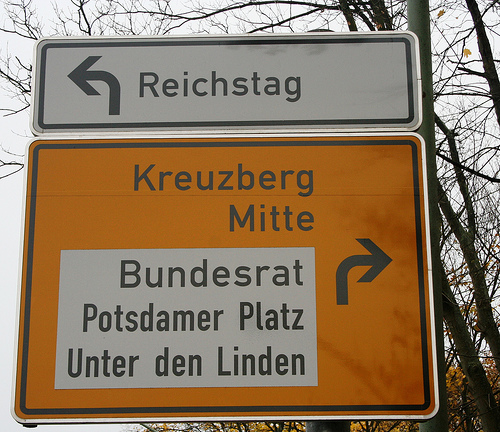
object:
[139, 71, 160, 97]
letter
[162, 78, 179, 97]
letter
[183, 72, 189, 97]
letter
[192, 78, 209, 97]
letter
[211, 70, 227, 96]
letter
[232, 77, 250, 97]
letter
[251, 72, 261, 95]
letter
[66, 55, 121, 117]
arrow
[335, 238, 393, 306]
arrow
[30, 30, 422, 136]
sign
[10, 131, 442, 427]
sign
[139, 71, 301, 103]
writing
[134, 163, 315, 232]
writing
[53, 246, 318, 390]
box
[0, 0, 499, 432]
sky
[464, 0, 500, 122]
tree trunk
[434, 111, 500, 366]
tree trunk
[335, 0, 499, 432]
tree trunk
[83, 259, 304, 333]
bundesrat potsdamer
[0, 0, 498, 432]
trees